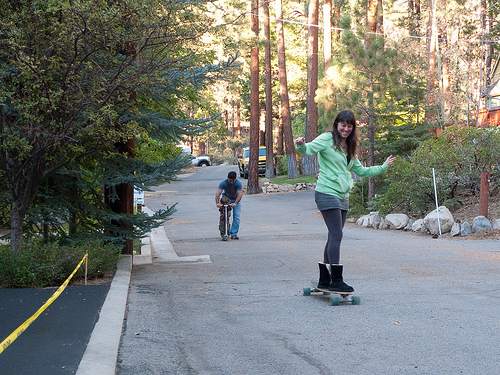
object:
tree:
[13, 11, 188, 262]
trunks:
[241, 7, 307, 195]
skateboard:
[311, 279, 360, 308]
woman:
[303, 113, 377, 286]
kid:
[218, 198, 233, 229]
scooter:
[217, 229, 236, 241]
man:
[218, 170, 252, 205]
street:
[172, 146, 285, 374]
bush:
[19, 237, 121, 266]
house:
[437, 87, 500, 167]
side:
[409, 20, 445, 205]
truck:
[240, 139, 282, 172]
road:
[236, 149, 292, 296]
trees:
[0, 0, 64, 260]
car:
[235, 132, 277, 180]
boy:
[215, 198, 239, 243]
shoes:
[327, 265, 354, 294]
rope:
[9, 255, 89, 327]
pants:
[317, 215, 348, 261]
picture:
[23, 19, 493, 341]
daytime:
[201, 32, 371, 79]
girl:
[309, 113, 373, 206]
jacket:
[315, 143, 366, 195]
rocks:
[421, 206, 454, 231]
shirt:
[221, 210, 235, 220]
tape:
[17, 256, 85, 343]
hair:
[343, 109, 360, 136]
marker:
[158, 221, 205, 272]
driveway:
[4, 288, 67, 371]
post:
[427, 170, 446, 244]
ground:
[389, 225, 500, 259]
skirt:
[309, 189, 354, 211]